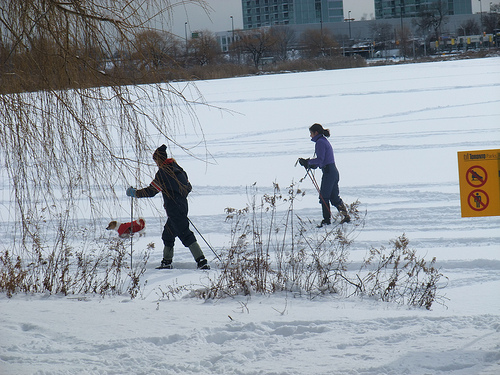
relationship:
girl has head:
[297, 124, 352, 229] [310, 122, 327, 138]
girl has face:
[297, 124, 352, 229] [309, 130, 316, 141]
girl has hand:
[297, 124, 352, 229] [299, 157, 308, 167]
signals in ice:
[453, 146, 499, 218] [1, 56, 499, 373]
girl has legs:
[297, 124, 352, 229] [313, 168, 351, 228]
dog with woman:
[106, 219, 160, 257] [297, 123, 353, 230]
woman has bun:
[297, 123, 353, 230] [322, 127, 331, 140]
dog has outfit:
[106, 219, 160, 257] [119, 220, 143, 238]